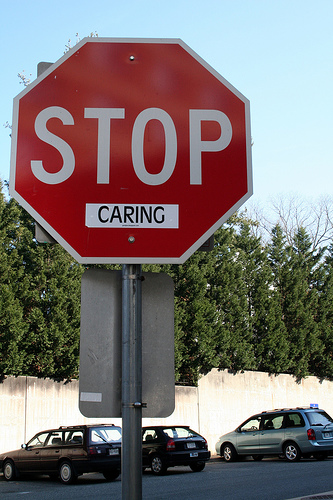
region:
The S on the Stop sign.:
[29, 106, 82, 184]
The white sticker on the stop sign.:
[85, 205, 179, 225]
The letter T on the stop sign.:
[79, 98, 127, 188]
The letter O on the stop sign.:
[130, 106, 178, 188]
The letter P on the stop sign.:
[181, 105, 233, 188]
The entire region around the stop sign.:
[4, 38, 265, 268]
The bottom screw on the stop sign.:
[121, 234, 138, 245]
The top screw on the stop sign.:
[126, 52, 144, 60]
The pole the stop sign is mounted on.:
[119, 262, 147, 497]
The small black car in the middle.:
[136, 425, 211, 473]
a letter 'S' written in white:
[28, 104, 81, 185]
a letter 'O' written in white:
[129, 104, 178, 185]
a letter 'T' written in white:
[80, 99, 131, 189]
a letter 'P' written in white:
[186, 104, 228, 188]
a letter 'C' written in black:
[97, 202, 107, 222]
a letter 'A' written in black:
[109, 205, 122, 224]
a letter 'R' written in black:
[122, 204, 133, 223]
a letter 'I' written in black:
[135, 207, 140, 224]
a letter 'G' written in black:
[153, 204, 163, 223]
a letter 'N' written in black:
[140, 204, 152, 223]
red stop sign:
[1, 21, 258, 274]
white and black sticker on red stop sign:
[71, 195, 188, 234]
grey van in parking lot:
[212, 402, 331, 466]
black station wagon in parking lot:
[1, 419, 121, 485]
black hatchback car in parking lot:
[141, 421, 211, 478]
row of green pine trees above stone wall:
[198, 282, 331, 384]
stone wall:
[189, 396, 236, 418]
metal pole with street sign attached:
[82, 268, 174, 498]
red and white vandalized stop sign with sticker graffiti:
[6, 32, 258, 270]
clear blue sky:
[239, 21, 317, 73]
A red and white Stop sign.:
[6, 32, 269, 272]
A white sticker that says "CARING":
[75, 200, 184, 231]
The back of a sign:
[68, 265, 189, 428]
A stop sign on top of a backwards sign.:
[3, 32, 261, 428]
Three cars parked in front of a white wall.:
[2, 400, 331, 478]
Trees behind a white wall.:
[2, 24, 331, 388]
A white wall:
[6, 361, 330, 459]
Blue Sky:
[2, 4, 329, 210]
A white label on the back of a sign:
[68, 386, 110, 409]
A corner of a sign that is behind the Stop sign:
[20, 43, 69, 85]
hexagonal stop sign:
[16, 29, 254, 273]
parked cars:
[15, 409, 323, 483]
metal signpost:
[118, 268, 147, 498]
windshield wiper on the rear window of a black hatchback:
[174, 430, 203, 442]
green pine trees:
[193, 292, 325, 368]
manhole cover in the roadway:
[301, 492, 330, 499]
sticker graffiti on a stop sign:
[76, 194, 191, 235]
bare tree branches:
[258, 187, 332, 222]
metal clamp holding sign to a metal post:
[117, 397, 151, 414]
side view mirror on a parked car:
[15, 433, 32, 455]